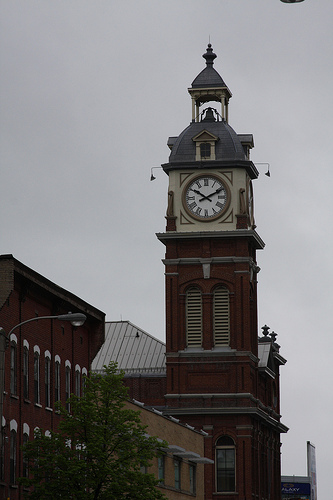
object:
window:
[43, 355, 50, 407]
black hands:
[199, 188, 222, 201]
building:
[155, 33, 289, 498]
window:
[226, 448, 236, 470]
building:
[0, 253, 106, 498]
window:
[206, 142, 213, 150]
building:
[88, 390, 208, 498]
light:
[59, 312, 88, 326]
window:
[189, 465, 196, 496]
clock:
[181, 172, 232, 224]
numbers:
[203, 177, 209, 188]